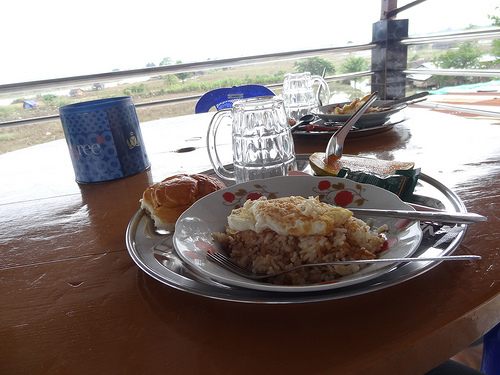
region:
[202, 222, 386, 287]
browned rice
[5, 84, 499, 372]
shiny brown painted wooden table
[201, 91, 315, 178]
upside down transparent glass cup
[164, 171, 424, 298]
white ceramic plate with red roses painted on it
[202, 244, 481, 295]
silver metal fork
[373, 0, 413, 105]
reflective post fro gaurdrail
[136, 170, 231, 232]
golden topped white roll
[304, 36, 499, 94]
grouping of sparse green trees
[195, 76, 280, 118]
blue plastic chair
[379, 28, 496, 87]
silver metal guard rail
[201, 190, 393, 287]
rice dish on a plate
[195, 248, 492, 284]
silver fork in a bowl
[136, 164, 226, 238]
roll on a plate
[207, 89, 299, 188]
glass mug on a table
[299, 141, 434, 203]
fruit on a plate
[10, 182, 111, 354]
wooden table where food is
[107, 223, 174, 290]
plate where bowl of food is on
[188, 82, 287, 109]
top of a blue chair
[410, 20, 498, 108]
metal fence behind table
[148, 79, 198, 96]
green bushes in the background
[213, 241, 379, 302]
Silver fork on plate.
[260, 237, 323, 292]
Rice on plate near fork.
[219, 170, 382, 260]
White plate has red floral print on it.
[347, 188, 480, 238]
silver knife on plate.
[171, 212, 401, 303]
White dish is sitting on a larger plate.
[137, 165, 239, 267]
Biscuit is sitting on the edge of plate.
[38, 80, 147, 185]
Blue container is sitting on table.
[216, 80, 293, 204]
Clear glass on table.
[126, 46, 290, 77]
Silver railing near table.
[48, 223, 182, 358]
Brown table under plates.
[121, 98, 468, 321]
Cup upside down on plate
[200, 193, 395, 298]
Food with white stuff on top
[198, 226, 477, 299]
Fork laying on plate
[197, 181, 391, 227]
Red flowers on white bowl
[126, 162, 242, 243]
Piece of bread on side of plate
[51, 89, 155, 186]
Blue canister on table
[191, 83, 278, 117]
Top of a blue chair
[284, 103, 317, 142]
Spoon on second plate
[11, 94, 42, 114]
Blue tent on the ground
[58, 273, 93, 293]
Nick out of table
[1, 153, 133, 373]
a wooden table with a shiny finish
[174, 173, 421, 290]
a floral design ceramic plate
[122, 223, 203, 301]
a silver serving tray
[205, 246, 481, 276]
a metal fork on the plate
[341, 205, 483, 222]
a metal knife on the plate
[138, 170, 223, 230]
a dinner roll on the serving tray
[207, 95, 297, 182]
a clear glass mug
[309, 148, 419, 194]
a slice of a cantaloupe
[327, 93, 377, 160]
a fruit spoon in the canteloupe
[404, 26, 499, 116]
metal rails on the balcony